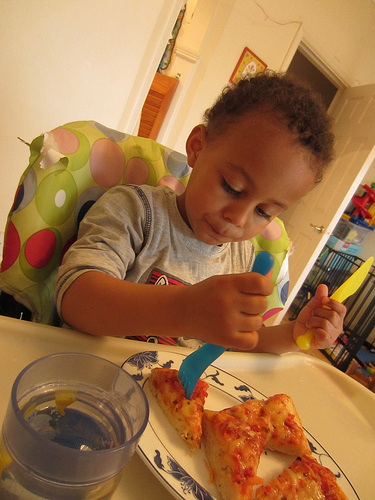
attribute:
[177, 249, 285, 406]
fork — blue 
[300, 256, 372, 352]
knife — yellow 